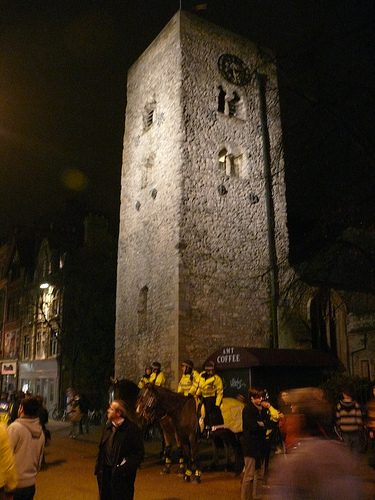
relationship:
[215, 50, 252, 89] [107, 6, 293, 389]
clock on tower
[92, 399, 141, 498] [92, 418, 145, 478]
man with jacket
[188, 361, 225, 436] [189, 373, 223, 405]
policeman wearing jacket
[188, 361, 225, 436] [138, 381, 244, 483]
policeman on horse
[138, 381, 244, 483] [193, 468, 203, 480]
horse wearing bootie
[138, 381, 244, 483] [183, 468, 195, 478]
horse wearing bootie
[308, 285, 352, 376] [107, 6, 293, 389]
entrance to tower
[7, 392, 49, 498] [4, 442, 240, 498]
person on street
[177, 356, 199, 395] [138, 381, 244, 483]
policeman riding horse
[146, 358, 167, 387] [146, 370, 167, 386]
policeman wearing jacket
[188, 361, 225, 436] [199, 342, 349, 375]
policeman near awning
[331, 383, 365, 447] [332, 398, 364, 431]
person wearing hoodie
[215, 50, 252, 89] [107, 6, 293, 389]
clock top of tower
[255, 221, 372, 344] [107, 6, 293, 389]
tree next to tower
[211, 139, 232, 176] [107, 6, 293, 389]
window on tower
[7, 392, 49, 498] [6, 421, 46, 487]
person wearing hoodie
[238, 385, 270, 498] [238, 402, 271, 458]
person wearing coat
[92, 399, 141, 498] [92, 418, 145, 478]
man wearing jacket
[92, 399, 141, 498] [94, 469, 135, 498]
man wearing pants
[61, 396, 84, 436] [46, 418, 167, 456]
person on sidewalk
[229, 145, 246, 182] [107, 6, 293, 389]
window in tower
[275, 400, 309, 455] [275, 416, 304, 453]
woman wearing dress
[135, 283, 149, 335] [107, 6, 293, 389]
window in tower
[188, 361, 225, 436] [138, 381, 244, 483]
policeman riding horse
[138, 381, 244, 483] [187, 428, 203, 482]
horse has leg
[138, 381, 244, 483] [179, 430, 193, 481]
horse has leg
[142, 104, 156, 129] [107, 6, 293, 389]
vent in tower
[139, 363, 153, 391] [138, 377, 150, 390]
policeman wearing vest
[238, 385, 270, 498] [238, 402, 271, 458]
man wearing coat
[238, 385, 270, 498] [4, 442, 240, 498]
man on street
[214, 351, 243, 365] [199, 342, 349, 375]
text on awning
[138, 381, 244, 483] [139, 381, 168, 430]
horse has head